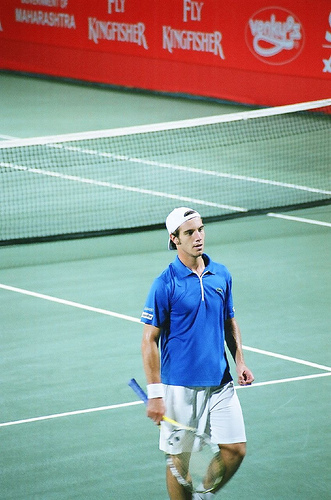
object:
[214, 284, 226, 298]
alligator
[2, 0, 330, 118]
banner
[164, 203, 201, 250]
cap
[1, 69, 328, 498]
court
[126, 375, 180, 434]
handle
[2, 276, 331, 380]
line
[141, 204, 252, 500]
man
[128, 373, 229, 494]
racket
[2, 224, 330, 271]
shadow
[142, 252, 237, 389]
shirt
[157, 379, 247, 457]
shorts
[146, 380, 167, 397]
wrist band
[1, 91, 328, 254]
net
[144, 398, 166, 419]
hand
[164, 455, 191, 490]
edge